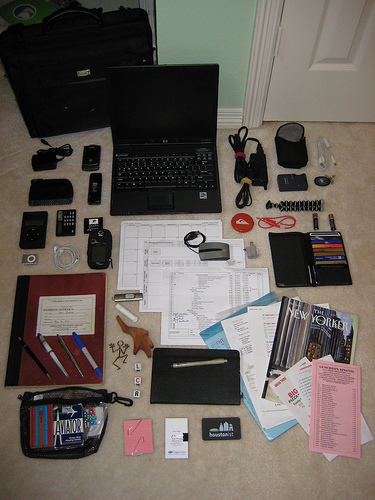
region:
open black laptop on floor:
[100, 57, 244, 220]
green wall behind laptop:
[167, 10, 244, 83]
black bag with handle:
[4, 7, 164, 135]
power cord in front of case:
[28, 135, 76, 173]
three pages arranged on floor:
[115, 216, 271, 350]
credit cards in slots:
[309, 228, 347, 273]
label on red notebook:
[33, 289, 97, 342]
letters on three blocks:
[132, 357, 144, 399]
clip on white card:
[162, 415, 195, 465]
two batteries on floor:
[303, 208, 346, 231]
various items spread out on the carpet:
[3, 4, 372, 473]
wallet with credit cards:
[263, 227, 354, 287]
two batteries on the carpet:
[300, 206, 345, 230]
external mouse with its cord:
[177, 220, 231, 261]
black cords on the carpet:
[217, 118, 269, 208]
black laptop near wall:
[106, 31, 222, 213]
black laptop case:
[3, 1, 158, 138]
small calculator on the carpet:
[47, 204, 78, 239]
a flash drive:
[106, 285, 143, 304]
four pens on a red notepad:
[0, 269, 110, 386]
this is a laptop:
[105, 68, 227, 218]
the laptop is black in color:
[114, 73, 199, 206]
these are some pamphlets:
[289, 356, 372, 467]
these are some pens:
[17, 323, 105, 378]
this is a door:
[287, 11, 354, 119]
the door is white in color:
[299, 15, 336, 89]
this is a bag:
[13, 33, 66, 123]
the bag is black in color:
[28, 34, 74, 125]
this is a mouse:
[190, 229, 233, 261]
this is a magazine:
[295, 305, 352, 344]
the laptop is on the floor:
[108, 78, 218, 213]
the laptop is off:
[106, 70, 219, 210]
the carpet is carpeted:
[98, 466, 289, 488]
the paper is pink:
[312, 359, 363, 457]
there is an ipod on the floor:
[19, 211, 49, 250]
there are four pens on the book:
[16, 335, 104, 382]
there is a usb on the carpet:
[112, 292, 162, 313]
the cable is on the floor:
[231, 130, 266, 210]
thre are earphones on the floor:
[55, 242, 90, 273]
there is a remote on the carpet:
[85, 176, 108, 208]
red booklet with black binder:
[8, 272, 109, 388]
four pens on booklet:
[13, 327, 103, 380]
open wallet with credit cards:
[267, 231, 355, 291]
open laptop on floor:
[99, 66, 226, 219]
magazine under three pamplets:
[265, 293, 366, 415]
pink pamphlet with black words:
[301, 356, 363, 460]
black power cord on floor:
[226, 126, 273, 210]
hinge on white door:
[268, 20, 287, 69]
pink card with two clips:
[122, 414, 154, 460]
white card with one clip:
[161, 414, 193, 464]